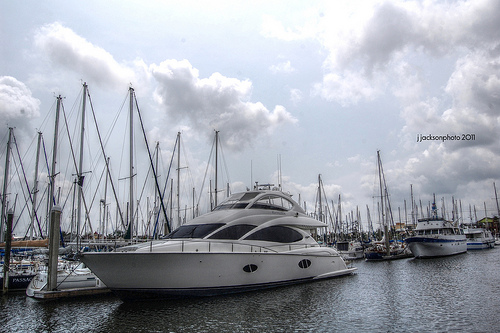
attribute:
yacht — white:
[73, 187, 357, 315]